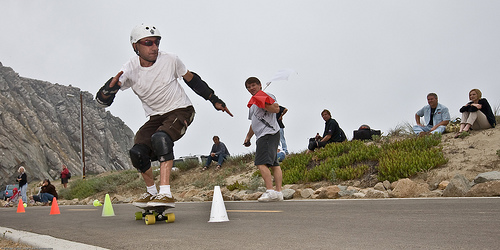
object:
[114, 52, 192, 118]
shirt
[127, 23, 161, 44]
helmet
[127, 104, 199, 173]
shorts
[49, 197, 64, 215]
orange cones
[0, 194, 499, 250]
road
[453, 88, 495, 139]
people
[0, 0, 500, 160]
sky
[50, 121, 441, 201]
grass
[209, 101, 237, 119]
hand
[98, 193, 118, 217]
cone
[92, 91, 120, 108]
arm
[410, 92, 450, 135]
man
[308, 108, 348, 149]
man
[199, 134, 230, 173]
man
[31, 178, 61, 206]
man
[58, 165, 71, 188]
man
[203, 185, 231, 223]
cone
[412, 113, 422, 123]
arm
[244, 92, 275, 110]
flag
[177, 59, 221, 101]
arm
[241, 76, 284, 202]
man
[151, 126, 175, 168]
knee cap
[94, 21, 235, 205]
he